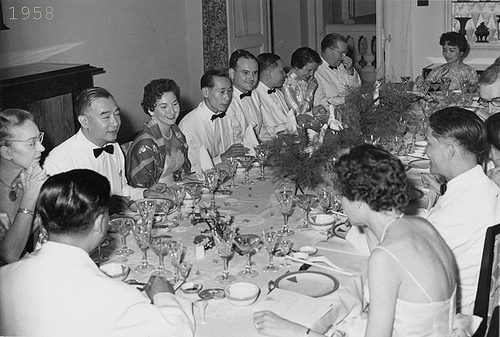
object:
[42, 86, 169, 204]
person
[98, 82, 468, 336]
table cloth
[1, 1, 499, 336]
picture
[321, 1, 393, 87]
door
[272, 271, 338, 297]
plate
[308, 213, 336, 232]
bowl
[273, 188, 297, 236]
wine glass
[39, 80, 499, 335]
table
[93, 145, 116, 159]
tie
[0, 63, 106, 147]
desk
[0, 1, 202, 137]
wall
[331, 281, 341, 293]
edge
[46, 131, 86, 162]
shoulder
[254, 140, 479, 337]
person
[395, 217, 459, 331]
back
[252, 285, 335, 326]
paper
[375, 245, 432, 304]
string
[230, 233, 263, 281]
glass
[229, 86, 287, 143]
jacket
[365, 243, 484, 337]
dress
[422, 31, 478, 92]
woman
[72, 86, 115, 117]
short haircut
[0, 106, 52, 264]
woman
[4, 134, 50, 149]
glasses